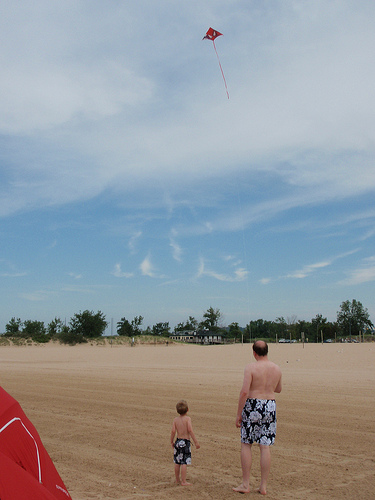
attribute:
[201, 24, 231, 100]
kite — red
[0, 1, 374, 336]
sky — bright, blue, clear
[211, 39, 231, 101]
string — long, red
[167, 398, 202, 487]
boy — barefoot, blonde haired, standing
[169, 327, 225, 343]
beach house — large, white, distant, low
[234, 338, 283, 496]
man — barefoot, balding, brown haired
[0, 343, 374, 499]
sand — brown, beach, smooth, moist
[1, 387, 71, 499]
tent — large, red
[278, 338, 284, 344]
car — in lot, parked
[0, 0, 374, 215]
cloud — soft, white, wispy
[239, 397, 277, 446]
shorts — flower patterned, black, white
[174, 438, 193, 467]
shorts — black, white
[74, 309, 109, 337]
tree — bushy, green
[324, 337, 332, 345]
car — parked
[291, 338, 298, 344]
car — parked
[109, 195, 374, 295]
cloud — scattered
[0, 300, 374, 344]
shoreline — bushy